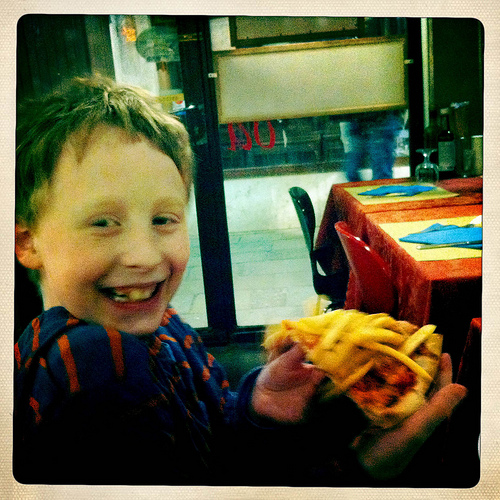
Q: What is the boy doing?
A: Smiling.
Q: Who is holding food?
A: Young boy.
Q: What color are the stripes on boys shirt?
A: Orange.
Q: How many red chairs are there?
A: One.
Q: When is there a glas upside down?
A: Table by window.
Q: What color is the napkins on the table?
A: Blue.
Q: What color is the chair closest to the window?
A: Green.